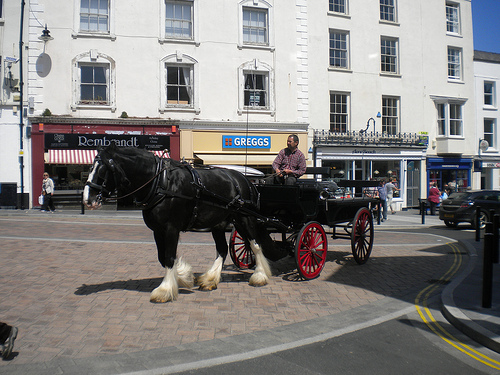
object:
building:
[0, 0, 476, 206]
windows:
[80, 66, 95, 83]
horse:
[77, 141, 271, 304]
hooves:
[147, 279, 180, 304]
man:
[269, 132, 306, 184]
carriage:
[82, 140, 382, 304]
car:
[437, 189, 500, 229]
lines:
[420, 284, 499, 367]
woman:
[38, 171, 59, 214]